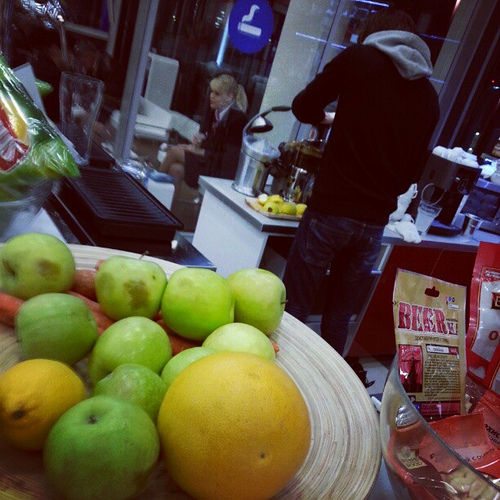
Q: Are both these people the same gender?
A: No, they are both male and female.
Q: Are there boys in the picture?
A: No, there are no boys.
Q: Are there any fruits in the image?
A: Yes, there is a fruit.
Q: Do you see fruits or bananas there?
A: Yes, there is a fruit.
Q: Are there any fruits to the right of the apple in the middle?
A: Yes, there is a fruit to the right of the apple.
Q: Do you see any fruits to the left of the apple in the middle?
A: No, the fruit is to the right of the apple.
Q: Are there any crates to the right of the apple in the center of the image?
A: No, there is a fruit to the right of the apple.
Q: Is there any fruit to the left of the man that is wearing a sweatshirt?
A: Yes, there is a fruit to the left of the man.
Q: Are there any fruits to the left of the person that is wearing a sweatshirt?
A: Yes, there is a fruit to the left of the man.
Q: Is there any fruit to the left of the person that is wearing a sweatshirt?
A: Yes, there is a fruit to the left of the man.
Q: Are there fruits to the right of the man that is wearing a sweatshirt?
A: No, the fruit is to the left of the man.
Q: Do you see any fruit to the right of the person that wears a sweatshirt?
A: No, the fruit is to the left of the man.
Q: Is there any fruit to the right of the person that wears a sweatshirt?
A: No, the fruit is to the left of the man.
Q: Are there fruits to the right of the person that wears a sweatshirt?
A: No, the fruit is to the left of the man.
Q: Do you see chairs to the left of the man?
A: No, there is a fruit to the left of the man.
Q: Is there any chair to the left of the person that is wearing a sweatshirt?
A: No, there is a fruit to the left of the man.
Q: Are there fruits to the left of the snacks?
A: Yes, there is a fruit to the left of the snacks.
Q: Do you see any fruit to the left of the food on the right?
A: Yes, there is a fruit to the left of the snacks.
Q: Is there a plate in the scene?
A: Yes, there is a plate.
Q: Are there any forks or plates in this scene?
A: Yes, there is a plate.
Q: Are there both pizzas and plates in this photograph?
A: No, there is a plate but no pizzas.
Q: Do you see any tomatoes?
A: No, there are no tomatoes.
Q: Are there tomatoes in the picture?
A: No, there are no tomatoes.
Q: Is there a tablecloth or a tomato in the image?
A: No, there are no tomatoes or tablecloths.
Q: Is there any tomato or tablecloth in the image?
A: No, there are no tomatoes or tablecloths.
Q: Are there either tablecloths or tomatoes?
A: No, there are no tomatoes or tablecloths.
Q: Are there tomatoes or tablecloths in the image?
A: No, there are no tomatoes or tablecloths.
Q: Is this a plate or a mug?
A: This is a plate.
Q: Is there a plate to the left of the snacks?
A: Yes, there is a plate to the left of the snacks.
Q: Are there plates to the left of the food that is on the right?
A: Yes, there is a plate to the left of the snacks.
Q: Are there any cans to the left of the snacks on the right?
A: No, there is a plate to the left of the snacks.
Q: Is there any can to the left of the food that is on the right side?
A: No, there is a plate to the left of the snacks.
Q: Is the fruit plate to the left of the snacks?
A: Yes, the plate is to the left of the snacks.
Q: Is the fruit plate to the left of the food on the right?
A: Yes, the plate is to the left of the snacks.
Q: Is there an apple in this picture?
A: Yes, there is an apple.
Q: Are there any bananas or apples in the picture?
A: Yes, there is an apple.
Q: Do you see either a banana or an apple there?
A: Yes, there is an apple.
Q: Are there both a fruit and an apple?
A: Yes, there are both an apple and a fruit.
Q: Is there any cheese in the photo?
A: No, there is no cheese.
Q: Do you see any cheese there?
A: No, there is no cheese.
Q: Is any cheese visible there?
A: No, there is no cheese.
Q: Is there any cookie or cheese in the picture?
A: No, there are no cheese or cookies.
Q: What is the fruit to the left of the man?
A: The fruit is an apple.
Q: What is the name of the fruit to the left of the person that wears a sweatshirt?
A: The fruit is an apple.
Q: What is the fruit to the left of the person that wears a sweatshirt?
A: The fruit is an apple.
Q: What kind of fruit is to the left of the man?
A: The fruit is an apple.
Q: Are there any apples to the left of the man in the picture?
A: Yes, there is an apple to the left of the man.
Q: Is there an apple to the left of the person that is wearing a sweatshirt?
A: Yes, there is an apple to the left of the man.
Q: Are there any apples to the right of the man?
A: No, the apple is to the left of the man.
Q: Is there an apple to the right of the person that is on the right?
A: No, the apple is to the left of the man.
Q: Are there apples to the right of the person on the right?
A: No, the apple is to the left of the man.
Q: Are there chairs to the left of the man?
A: No, there is an apple to the left of the man.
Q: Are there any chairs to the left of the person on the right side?
A: No, there is an apple to the left of the man.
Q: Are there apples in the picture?
A: Yes, there is an apple.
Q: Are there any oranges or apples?
A: Yes, there is an apple.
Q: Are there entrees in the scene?
A: No, there are no entrees.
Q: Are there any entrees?
A: No, there are no entrees.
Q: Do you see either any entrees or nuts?
A: No, there are no entrees or nuts.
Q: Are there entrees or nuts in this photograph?
A: No, there are no entrees or nuts.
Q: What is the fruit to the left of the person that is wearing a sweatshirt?
A: The fruit is an apple.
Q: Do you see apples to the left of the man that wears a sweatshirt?
A: Yes, there is an apple to the left of the man.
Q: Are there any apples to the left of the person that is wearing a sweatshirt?
A: Yes, there is an apple to the left of the man.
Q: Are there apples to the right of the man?
A: No, the apple is to the left of the man.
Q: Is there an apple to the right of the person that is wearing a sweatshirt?
A: No, the apple is to the left of the man.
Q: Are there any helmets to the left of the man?
A: No, there is an apple to the left of the man.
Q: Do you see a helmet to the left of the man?
A: No, there is an apple to the left of the man.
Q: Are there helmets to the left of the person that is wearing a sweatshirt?
A: No, there is an apple to the left of the man.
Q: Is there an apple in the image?
A: Yes, there is an apple.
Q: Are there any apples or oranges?
A: Yes, there is an apple.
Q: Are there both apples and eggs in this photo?
A: No, there is an apple but no eggs.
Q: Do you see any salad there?
A: No, there is no salad.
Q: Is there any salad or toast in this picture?
A: No, there are no salad or toasts.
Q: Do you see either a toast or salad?
A: No, there are no salad or toasts.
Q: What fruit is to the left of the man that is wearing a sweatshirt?
A: The fruit is an apple.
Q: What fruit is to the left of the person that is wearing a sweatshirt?
A: The fruit is an apple.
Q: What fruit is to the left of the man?
A: The fruit is an apple.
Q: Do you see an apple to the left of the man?
A: Yes, there is an apple to the left of the man.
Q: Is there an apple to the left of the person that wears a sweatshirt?
A: Yes, there is an apple to the left of the man.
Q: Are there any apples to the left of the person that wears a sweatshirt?
A: Yes, there is an apple to the left of the man.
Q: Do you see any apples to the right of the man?
A: No, the apple is to the left of the man.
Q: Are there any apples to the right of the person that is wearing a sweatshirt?
A: No, the apple is to the left of the man.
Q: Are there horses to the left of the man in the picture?
A: No, there is an apple to the left of the man.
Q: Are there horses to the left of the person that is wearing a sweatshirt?
A: No, there is an apple to the left of the man.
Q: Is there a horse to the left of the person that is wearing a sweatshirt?
A: No, there is an apple to the left of the man.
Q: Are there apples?
A: Yes, there is an apple.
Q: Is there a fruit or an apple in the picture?
A: Yes, there is an apple.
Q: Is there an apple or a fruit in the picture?
A: Yes, there is an apple.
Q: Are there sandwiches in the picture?
A: No, there are no sandwiches.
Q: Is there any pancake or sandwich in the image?
A: No, there are no sandwiches or pancakes.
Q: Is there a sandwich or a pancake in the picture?
A: No, there are no sandwiches or pancakes.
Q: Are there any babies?
A: No, there are no babies.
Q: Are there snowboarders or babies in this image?
A: No, there are no babies or snowboarders.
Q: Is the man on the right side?
A: Yes, the man is on the right of the image.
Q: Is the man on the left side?
A: No, the man is on the right of the image.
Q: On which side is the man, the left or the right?
A: The man is on the right of the image.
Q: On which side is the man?
A: The man is on the right of the image.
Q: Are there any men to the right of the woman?
A: Yes, there is a man to the right of the woman.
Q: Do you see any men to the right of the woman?
A: Yes, there is a man to the right of the woman.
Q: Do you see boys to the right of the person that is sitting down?
A: No, there is a man to the right of the woman.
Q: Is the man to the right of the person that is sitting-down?
A: Yes, the man is to the right of the woman.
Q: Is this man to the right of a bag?
A: No, the man is to the right of the woman.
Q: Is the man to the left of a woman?
A: No, the man is to the right of a woman.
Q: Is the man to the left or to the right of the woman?
A: The man is to the right of the woman.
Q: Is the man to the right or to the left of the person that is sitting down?
A: The man is to the right of the woman.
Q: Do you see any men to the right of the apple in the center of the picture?
A: Yes, there is a man to the right of the apple.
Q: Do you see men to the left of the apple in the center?
A: No, the man is to the right of the apple.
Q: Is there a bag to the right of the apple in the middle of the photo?
A: No, there is a man to the right of the apple.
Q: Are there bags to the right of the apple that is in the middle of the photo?
A: No, there is a man to the right of the apple.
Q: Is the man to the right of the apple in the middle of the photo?
A: Yes, the man is to the right of the apple.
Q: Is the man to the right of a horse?
A: No, the man is to the right of the apple.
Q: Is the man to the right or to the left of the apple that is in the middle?
A: The man is to the right of the apple.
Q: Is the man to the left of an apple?
A: No, the man is to the right of an apple.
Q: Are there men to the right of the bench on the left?
A: Yes, there is a man to the right of the bench.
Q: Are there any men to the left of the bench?
A: No, the man is to the right of the bench.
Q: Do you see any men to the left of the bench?
A: No, the man is to the right of the bench.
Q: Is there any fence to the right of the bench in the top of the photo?
A: No, there is a man to the right of the bench.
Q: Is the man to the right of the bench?
A: Yes, the man is to the right of the bench.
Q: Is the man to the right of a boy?
A: No, the man is to the right of the bench.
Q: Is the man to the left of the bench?
A: No, the man is to the right of the bench.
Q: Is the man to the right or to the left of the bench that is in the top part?
A: The man is to the right of the bench.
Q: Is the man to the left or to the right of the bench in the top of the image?
A: The man is to the right of the bench.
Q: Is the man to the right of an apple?
A: Yes, the man is to the right of an apple.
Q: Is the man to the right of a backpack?
A: No, the man is to the right of an apple.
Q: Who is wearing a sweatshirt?
A: The man is wearing a sweatshirt.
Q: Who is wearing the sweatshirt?
A: The man is wearing a sweatshirt.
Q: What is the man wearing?
A: The man is wearing a sweatshirt.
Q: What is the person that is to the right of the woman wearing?
A: The man is wearing a sweatshirt.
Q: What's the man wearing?
A: The man is wearing a sweatshirt.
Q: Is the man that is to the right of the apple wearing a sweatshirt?
A: Yes, the man is wearing a sweatshirt.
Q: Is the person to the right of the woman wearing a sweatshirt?
A: Yes, the man is wearing a sweatshirt.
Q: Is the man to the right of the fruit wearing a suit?
A: No, the man is wearing a sweatshirt.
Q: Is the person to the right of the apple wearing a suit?
A: No, the man is wearing a sweatshirt.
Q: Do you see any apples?
A: Yes, there is an apple.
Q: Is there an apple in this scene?
A: Yes, there is an apple.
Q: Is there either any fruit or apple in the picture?
A: Yes, there is an apple.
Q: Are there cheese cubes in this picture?
A: No, there are no cheese cubes.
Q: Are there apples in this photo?
A: Yes, there is an apple.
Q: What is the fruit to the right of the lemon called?
A: The fruit is an apple.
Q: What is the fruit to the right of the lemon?
A: The fruit is an apple.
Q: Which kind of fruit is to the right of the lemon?
A: The fruit is an apple.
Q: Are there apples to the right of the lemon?
A: Yes, there is an apple to the right of the lemon.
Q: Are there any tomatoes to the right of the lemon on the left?
A: No, there is an apple to the right of the lemon.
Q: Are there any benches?
A: Yes, there is a bench.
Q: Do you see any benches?
A: Yes, there is a bench.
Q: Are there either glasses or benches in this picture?
A: Yes, there is a bench.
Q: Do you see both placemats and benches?
A: No, there is a bench but no placemats.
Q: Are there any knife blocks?
A: No, there are no knife blocks.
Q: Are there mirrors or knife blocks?
A: No, there are no knife blocks or mirrors.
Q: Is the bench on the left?
A: Yes, the bench is on the left of the image.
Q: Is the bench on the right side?
A: No, the bench is on the left of the image.